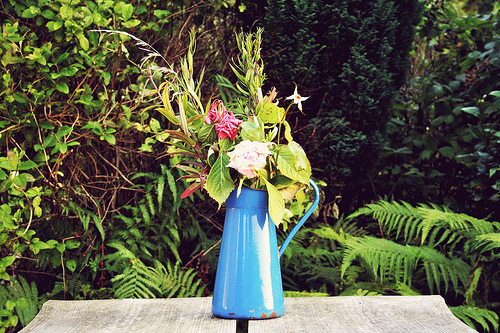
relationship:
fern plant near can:
[112, 258, 209, 299] [212, 179, 320, 319]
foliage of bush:
[3, 1, 500, 333] [23, 7, 198, 266]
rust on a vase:
[214, 304, 276, 320] [202, 172, 320, 319]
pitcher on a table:
[211, 181, 320, 317] [16, 292, 481, 332]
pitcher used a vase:
[212, 180, 319, 320] [156, 121, 398, 325]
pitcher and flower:
[211, 181, 320, 317] [224, 140, 271, 179]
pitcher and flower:
[211, 181, 320, 317] [206, 101, 238, 138]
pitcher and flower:
[211, 181, 320, 317] [285, 88, 310, 110]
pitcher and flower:
[211, 181, 320, 317] [175, 166, 209, 200]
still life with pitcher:
[142, 24, 327, 324] [211, 181, 320, 317]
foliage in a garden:
[3, 1, 498, 328] [3, 2, 498, 331]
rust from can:
[214, 304, 276, 320] [212, 179, 320, 319]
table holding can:
[13, 290, 236, 330] [206, 165, 328, 322]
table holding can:
[13, 294, 475, 333] [206, 165, 328, 322]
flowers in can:
[141, 24, 320, 212] [212, 179, 320, 319]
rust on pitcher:
[201, 303, 296, 321] [211, 181, 320, 317]